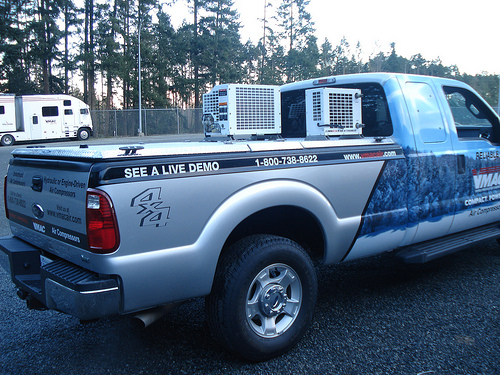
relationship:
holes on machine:
[234, 85, 276, 132] [201, 80, 283, 137]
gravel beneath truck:
[0, 215, 500, 374] [19, 62, 484, 357]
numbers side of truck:
[247, 157, 327, 166] [13, 38, 485, 369]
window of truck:
[448, 70, 497, 151] [19, 62, 484, 357]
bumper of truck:
[3, 267, 113, 320] [1, 72, 498, 332]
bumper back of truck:
[3, 267, 113, 320] [1, 72, 498, 332]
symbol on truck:
[129, 185, 172, 228] [19, 62, 484, 357]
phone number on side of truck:
[252, 154, 321, 166] [1, 72, 498, 332]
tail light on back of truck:
[86, 187, 117, 253] [49, 69, 494, 194]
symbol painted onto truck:
[129, 185, 172, 228] [19, 35, 499, 252]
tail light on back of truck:
[86, 187, 117, 253] [19, 62, 484, 357]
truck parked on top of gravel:
[1, 68, 498, 365] [330, 296, 489, 367]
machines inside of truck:
[193, 82, 369, 142] [1, 64, 498, 368]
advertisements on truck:
[123, 147, 398, 180] [1, 68, 498, 365]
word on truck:
[160, 162, 183, 181] [19, 62, 484, 357]